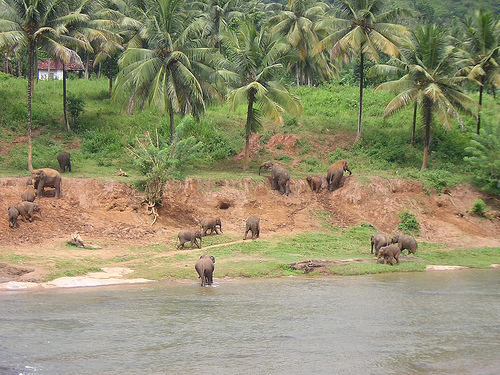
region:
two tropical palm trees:
[106, 0, 300, 158]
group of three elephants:
[363, 222, 424, 274]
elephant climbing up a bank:
[254, 155, 296, 197]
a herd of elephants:
[178, 148, 438, 302]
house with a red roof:
[21, 45, 91, 90]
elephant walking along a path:
[165, 225, 213, 254]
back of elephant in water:
[189, 252, 223, 302]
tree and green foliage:
[374, 43, 491, 175]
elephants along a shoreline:
[350, 226, 440, 283]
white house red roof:
[28, 46, 84, 91]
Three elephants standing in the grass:
[362, 223, 422, 270]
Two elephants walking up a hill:
[252, 140, 357, 200]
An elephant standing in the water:
[180, 251, 225, 291]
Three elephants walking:
[170, 205, 265, 250]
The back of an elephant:
[190, 255, 215, 290]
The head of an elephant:
[210, 211, 225, 231]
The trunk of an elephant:
[215, 221, 225, 231]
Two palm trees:
[112, 53, 310, 160]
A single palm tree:
[382, 56, 476, 173]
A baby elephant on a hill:
[13, 195, 50, 228]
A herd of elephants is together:
[5, 15, 475, 362]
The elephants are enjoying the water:
[0, 48, 475, 355]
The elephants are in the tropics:
[10, 8, 495, 361]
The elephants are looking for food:
[13, 30, 470, 360]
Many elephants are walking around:
[5, 15, 490, 372]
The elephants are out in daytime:
[25, 38, 481, 353]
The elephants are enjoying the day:
[35, 25, 472, 367]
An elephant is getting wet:
[11, 28, 464, 353]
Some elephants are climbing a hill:
[21, 37, 467, 372]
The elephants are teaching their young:
[5, 56, 486, 373]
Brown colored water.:
[3, 265, 499, 371]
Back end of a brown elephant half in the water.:
[193, 253, 214, 285]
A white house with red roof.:
[24, 51, 83, 80]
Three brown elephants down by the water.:
[368, 234, 416, 264]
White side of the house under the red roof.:
[35, 69, 65, 81]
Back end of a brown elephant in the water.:
[192, 253, 217, 288]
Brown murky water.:
[6, 273, 499, 373]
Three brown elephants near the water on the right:
[366, 230, 419, 264]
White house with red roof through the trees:
[26, 52, 85, 82]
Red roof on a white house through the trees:
[31, 53, 84, 73]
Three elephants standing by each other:
[368, 230, 420, 263]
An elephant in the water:
[195, 253, 214, 285]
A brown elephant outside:
[193, 253, 214, 287]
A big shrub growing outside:
[120, 113, 209, 205]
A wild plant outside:
[397, 207, 420, 236]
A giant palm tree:
[310, 1, 413, 144]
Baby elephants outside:
[2, 190, 43, 225]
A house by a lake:
[37, 56, 89, 78]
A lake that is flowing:
[0, 265, 498, 374]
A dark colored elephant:
[177, 229, 202, 246]